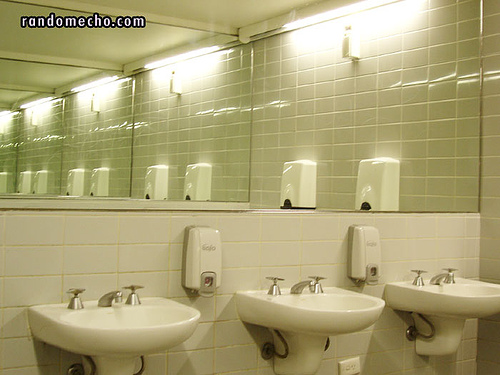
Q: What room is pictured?
A: It is a bathroom.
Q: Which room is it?
A: It is a bathroom.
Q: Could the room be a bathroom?
A: Yes, it is a bathroom.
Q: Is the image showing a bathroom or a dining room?
A: It is showing a bathroom.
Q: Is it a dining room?
A: No, it is a bathroom.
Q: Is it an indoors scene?
A: Yes, it is indoors.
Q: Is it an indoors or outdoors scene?
A: It is indoors.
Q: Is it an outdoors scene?
A: No, it is indoors.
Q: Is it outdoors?
A: No, it is indoors.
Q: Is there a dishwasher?
A: No, there are no dishwashers.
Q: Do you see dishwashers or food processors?
A: No, there are no dishwashers or food processors.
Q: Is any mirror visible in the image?
A: Yes, there is a mirror.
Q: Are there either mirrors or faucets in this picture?
A: Yes, there is a mirror.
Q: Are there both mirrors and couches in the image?
A: No, there is a mirror but no couches.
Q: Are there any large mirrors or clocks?
A: Yes, there is a large mirror.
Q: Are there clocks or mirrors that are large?
A: Yes, the mirror is large.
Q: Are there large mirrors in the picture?
A: Yes, there is a large mirror.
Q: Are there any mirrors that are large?
A: Yes, there is a mirror that is large.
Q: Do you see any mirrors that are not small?
A: Yes, there is a large mirror.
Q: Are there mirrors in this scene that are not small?
A: Yes, there is a large mirror.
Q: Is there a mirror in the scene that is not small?
A: Yes, there is a large mirror.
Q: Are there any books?
A: No, there are no books.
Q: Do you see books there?
A: No, there are no books.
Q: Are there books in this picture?
A: No, there are no books.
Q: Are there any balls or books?
A: No, there are no books or balls.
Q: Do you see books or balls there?
A: No, there are no books or balls.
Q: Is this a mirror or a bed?
A: This is a mirror.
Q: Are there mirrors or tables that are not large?
A: No, there is a mirror but it is large.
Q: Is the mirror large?
A: Yes, the mirror is large.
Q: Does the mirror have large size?
A: Yes, the mirror is large.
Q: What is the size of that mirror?
A: The mirror is large.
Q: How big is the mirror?
A: The mirror is large.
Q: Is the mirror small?
A: No, the mirror is large.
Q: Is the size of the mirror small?
A: No, the mirror is large.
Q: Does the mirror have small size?
A: No, the mirror is large.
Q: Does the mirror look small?
A: No, the mirror is large.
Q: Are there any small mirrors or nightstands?
A: No, there is a mirror but it is large.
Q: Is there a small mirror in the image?
A: No, there is a mirror but it is large.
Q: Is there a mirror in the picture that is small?
A: No, there is a mirror but it is large.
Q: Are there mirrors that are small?
A: No, there is a mirror but it is large.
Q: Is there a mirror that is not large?
A: No, there is a mirror but it is large.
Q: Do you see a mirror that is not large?
A: No, there is a mirror but it is large.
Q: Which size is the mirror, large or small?
A: The mirror is large.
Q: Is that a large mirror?
A: Yes, that is a large mirror.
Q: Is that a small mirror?
A: No, that is a large mirror.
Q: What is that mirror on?
A: The mirror is on the wall.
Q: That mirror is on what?
A: The mirror is on the wall.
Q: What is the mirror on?
A: The mirror is on the wall.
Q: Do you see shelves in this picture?
A: No, there are no shelves.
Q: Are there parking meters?
A: No, there are no parking meters.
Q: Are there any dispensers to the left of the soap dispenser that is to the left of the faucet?
A: Yes, there is a dispenser to the left of the soap dispenser.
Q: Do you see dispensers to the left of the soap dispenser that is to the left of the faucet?
A: Yes, there is a dispenser to the left of the soap dispenser.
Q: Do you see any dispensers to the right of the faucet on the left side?
A: Yes, there is a dispenser to the right of the faucet.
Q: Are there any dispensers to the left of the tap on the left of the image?
A: No, the dispenser is to the right of the tap.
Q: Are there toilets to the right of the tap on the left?
A: No, there is a dispenser to the right of the tap.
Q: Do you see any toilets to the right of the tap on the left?
A: No, there is a dispenser to the right of the tap.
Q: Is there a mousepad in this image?
A: No, there are no mouse pads.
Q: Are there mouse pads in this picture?
A: No, there are no mouse pads.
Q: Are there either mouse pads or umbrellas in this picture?
A: No, there are no mouse pads or umbrellas.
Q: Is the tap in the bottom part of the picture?
A: Yes, the tap is in the bottom of the image.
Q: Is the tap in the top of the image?
A: No, the tap is in the bottom of the image.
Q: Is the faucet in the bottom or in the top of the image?
A: The faucet is in the bottom of the image.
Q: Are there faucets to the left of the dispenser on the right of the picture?
A: Yes, there is a faucet to the left of the dispenser.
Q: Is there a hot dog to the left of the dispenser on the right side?
A: No, there is a faucet to the left of the dispenser.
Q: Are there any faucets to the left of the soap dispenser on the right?
A: Yes, there is a faucet to the left of the soap dispenser.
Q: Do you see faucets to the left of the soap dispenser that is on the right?
A: Yes, there is a faucet to the left of the soap dispenser.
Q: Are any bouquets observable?
A: No, there are no bouquets.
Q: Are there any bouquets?
A: No, there are no bouquets.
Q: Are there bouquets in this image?
A: No, there are no bouquets.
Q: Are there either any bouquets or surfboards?
A: No, there are no bouquets or surfboards.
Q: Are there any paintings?
A: No, there are no paintings.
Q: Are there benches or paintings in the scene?
A: No, there are no paintings or benches.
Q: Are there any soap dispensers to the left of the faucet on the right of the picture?
A: Yes, there is a soap dispenser to the left of the tap.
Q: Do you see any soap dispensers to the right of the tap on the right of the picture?
A: No, the soap dispenser is to the left of the tap.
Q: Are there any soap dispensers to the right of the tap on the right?
A: No, the soap dispenser is to the left of the tap.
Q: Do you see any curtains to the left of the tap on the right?
A: No, there is a soap dispenser to the left of the faucet.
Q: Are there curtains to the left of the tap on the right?
A: No, there is a soap dispenser to the left of the faucet.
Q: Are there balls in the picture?
A: No, there are no balls.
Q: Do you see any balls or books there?
A: No, there are no balls or books.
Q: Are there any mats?
A: No, there are no mats.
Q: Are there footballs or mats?
A: No, there are no mats or footballs.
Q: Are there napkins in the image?
A: No, there are no napkins.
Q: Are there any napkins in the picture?
A: No, there are no napkins.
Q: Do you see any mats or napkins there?
A: No, there are no napkins or mats.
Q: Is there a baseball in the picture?
A: No, there are no baseballs.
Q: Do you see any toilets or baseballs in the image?
A: No, there are no baseballs or toilets.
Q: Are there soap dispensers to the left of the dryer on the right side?
A: Yes, there are soap dispensers to the left of the dryer.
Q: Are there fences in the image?
A: No, there are no fences.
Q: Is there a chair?
A: No, there are no chairs.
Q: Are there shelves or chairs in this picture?
A: No, there are no chairs or shelves.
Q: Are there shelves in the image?
A: No, there are no shelves.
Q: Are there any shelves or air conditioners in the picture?
A: No, there are no shelves or air conditioners.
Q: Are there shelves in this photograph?
A: No, there are no shelves.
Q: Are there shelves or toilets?
A: No, there are no shelves or toilets.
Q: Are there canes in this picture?
A: No, there are no canes.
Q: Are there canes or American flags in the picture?
A: No, there are no canes or American flags.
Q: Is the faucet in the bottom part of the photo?
A: Yes, the faucet is in the bottom of the image.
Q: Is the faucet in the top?
A: No, the faucet is in the bottom of the image.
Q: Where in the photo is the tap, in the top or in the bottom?
A: The tap is in the bottom of the image.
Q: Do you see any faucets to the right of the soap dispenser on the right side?
A: Yes, there is a faucet to the right of the soap dispenser.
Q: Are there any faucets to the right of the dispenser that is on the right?
A: Yes, there is a faucet to the right of the dispenser.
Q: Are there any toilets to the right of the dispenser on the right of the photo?
A: No, there is a faucet to the right of the dispenser.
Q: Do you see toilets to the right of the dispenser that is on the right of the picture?
A: No, there is a faucet to the right of the dispenser.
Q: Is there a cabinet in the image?
A: No, there are no cabinets.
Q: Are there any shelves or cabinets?
A: No, there are no cabinets or shelves.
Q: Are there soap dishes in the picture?
A: No, there are no soap dishes.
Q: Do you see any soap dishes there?
A: No, there are no soap dishes.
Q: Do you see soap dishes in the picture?
A: No, there are no soap dishes.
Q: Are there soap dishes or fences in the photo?
A: No, there are no soap dishes or fences.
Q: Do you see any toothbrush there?
A: No, there are no toothbrushes.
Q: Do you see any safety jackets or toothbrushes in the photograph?
A: No, there are no toothbrushes or safety jackets.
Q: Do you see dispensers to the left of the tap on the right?
A: Yes, there is a dispenser to the left of the tap.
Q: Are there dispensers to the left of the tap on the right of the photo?
A: Yes, there is a dispenser to the left of the tap.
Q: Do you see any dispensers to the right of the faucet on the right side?
A: No, the dispenser is to the left of the tap.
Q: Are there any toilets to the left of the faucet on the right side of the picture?
A: No, there is a dispenser to the left of the faucet.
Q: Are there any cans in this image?
A: No, there are no cans.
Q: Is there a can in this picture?
A: No, there are no cans.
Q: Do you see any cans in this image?
A: No, there are no cans.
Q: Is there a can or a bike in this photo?
A: No, there are no cans or bikes.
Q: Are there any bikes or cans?
A: No, there are no cans or bikes.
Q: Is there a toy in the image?
A: No, there are no toys.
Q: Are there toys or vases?
A: No, there are no toys or vases.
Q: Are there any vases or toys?
A: No, there are no toys or vases.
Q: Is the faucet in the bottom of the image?
A: Yes, the faucet is in the bottom of the image.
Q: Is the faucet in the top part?
A: No, the faucet is in the bottom of the image.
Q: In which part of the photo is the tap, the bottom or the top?
A: The tap is in the bottom of the image.